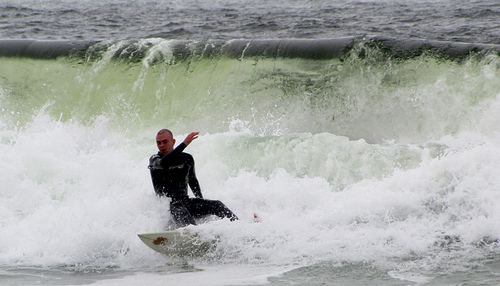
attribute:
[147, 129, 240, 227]
surfer — bald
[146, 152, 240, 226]
suit — black, wet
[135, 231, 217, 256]
surfboard — white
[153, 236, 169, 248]
logo — red, small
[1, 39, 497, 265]
wave — crashing, tall, white, large, medium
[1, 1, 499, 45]
water — dark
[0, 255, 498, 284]
water — white, foamy, chaotic, turbulent, rough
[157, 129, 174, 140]
hair — short, dark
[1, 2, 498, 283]
ocean — white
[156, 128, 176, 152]
head — shaven